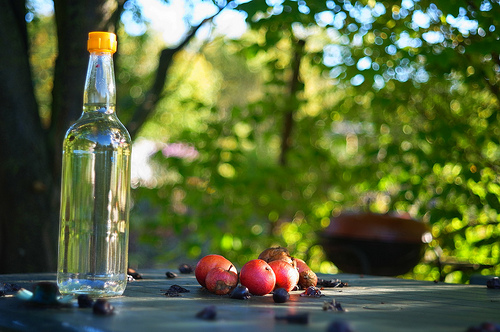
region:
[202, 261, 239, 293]
small apple on a table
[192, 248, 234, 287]
small apple on a table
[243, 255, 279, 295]
small apple on a table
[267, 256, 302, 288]
small apple on a table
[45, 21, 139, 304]
clear bottle on a table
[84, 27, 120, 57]
yellow cap on a bottle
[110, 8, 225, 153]
branch of a tree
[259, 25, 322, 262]
trunk of a tree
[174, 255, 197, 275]
small fruit on the table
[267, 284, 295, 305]
small fruit on the table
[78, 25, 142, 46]
The top of bottle is yellow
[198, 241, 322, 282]
Apples on the table.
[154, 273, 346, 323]
Berries scattered on the table.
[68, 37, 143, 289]
A bottle on the table.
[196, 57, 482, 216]
A big tree by the grill.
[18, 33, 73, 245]
Tree trunk is long.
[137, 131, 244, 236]
Building behind the trees.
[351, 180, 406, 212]
The handle on the grill.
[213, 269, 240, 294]
The apple looks like its rotten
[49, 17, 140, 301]
The clear glass bottle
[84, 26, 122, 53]
The yellow cap on the clear glass bottle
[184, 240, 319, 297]
The small apples on the table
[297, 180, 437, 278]
The out of focus barbeque grill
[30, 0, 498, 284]
The tree leaves behind the table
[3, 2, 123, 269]
The large tree trunk behind the glass bottle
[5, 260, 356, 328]
The berries on the table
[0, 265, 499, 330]
The table the items are on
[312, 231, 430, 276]
The black part of the barbeque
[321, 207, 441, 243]
The red part of the barbeque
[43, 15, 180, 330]
the bottle is clear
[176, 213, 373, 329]
fruits on the table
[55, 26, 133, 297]
Clear bottle on the table.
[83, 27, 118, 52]
Orange cap on the bottle.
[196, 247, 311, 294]
apples on the table.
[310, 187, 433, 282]
Charcoal grill in the background.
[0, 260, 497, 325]
Gray table in the forefront.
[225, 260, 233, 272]
Brown stem on the apple.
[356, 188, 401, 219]
Handle on the grill.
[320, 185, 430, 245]
Red lid on the grill.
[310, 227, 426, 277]
Black bottom on the grill.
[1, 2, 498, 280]
Trees in the background.